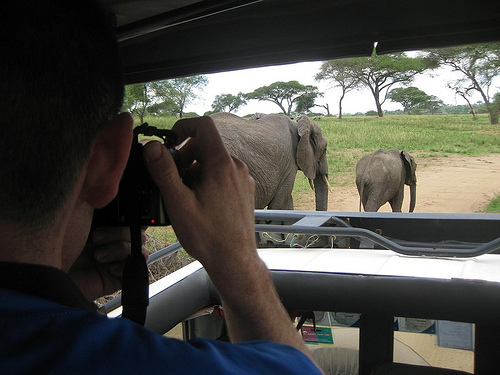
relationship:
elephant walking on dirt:
[354, 146, 428, 211] [420, 159, 483, 205]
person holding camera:
[16, 50, 269, 352] [115, 138, 215, 235]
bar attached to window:
[291, 221, 498, 265] [128, 58, 498, 273]